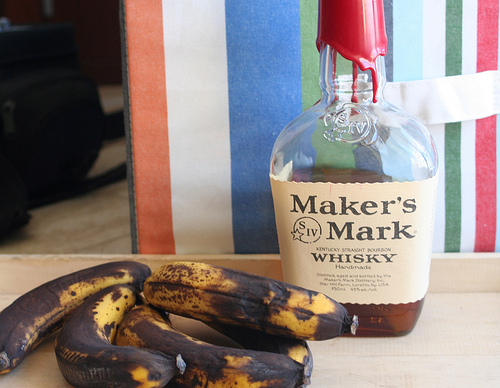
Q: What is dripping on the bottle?
A: Wax.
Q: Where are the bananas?
A: Next to bottle.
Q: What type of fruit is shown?
A: Bananas.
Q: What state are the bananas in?
A: Overripe.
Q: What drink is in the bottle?
A: Whiskey.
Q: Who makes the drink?
A: Maker's Mark.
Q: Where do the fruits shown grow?
A: Tree.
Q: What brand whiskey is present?
A: Maker's Mark.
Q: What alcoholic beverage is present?
A: Whisky.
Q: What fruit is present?
A: Bananas.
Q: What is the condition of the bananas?
A: Over ripe.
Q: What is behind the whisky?
A: Striped bag.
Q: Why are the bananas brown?
A: Rotting.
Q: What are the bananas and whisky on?
A: Counter.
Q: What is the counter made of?
A: Wood.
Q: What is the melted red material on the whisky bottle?
A: Wax.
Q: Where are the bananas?
A: On counter.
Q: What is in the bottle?
A: Whisky.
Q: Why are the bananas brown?
A: Rotten.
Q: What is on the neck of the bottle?
A: Wax.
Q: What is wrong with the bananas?
A: Overripe.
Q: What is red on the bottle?
A: Wax.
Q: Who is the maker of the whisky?
A: Maker's Mark.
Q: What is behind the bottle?
A: A striped bag.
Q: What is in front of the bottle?
A: Bananas.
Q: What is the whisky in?
A: A bottle.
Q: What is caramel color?
A: The whiskey.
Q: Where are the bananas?
A: Next to the Maker's Mark.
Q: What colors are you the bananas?
A: Brown and yellow.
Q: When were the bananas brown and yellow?
A: While they were sitting next to the Maker's Mark.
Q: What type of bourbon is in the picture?
A: Maker's Mark.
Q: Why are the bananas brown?
A: They're old.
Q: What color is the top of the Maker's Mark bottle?
A: Red.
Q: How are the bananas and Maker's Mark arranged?
A: Side by side.